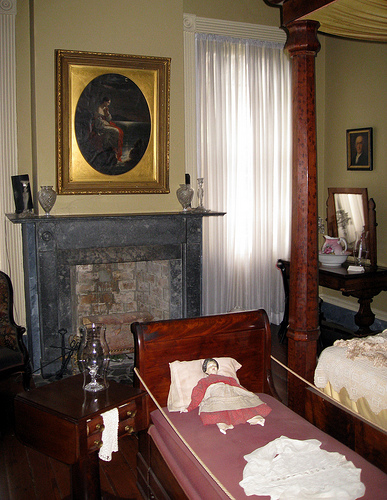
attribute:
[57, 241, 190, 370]
stone fireplace — grey, victorian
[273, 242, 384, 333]
table — wooden, end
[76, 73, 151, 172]
painting — oil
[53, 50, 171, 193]
mat — gold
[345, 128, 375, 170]
painting — small, guilt framed, Oil, former president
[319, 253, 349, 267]
basin — china flowered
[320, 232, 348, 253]
pitcher — china flowered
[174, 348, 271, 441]
china doll — antique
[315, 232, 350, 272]
vase — pink